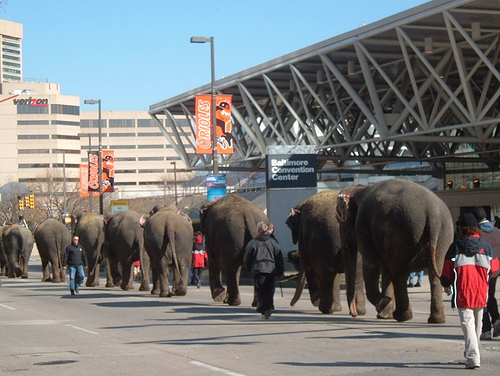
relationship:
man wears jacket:
[62, 234, 87, 296] [65, 244, 88, 268]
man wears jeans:
[62, 234, 87, 296] [66, 261, 86, 289]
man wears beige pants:
[438, 213, 499, 369] [452, 302, 488, 353]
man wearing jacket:
[442, 219, 496, 373] [439, 234, 500, 309]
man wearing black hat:
[438, 213, 499, 369] [455, 210, 479, 225]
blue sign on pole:
[206, 175, 226, 200] [207, 34, 229, 183]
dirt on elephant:
[307, 182, 339, 207] [279, 184, 367, 325]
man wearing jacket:
[466, 203, 498, 339] [468, 221, 497, 271]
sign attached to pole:
[190, 92, 237, 154] [209, 36, 219, 206]